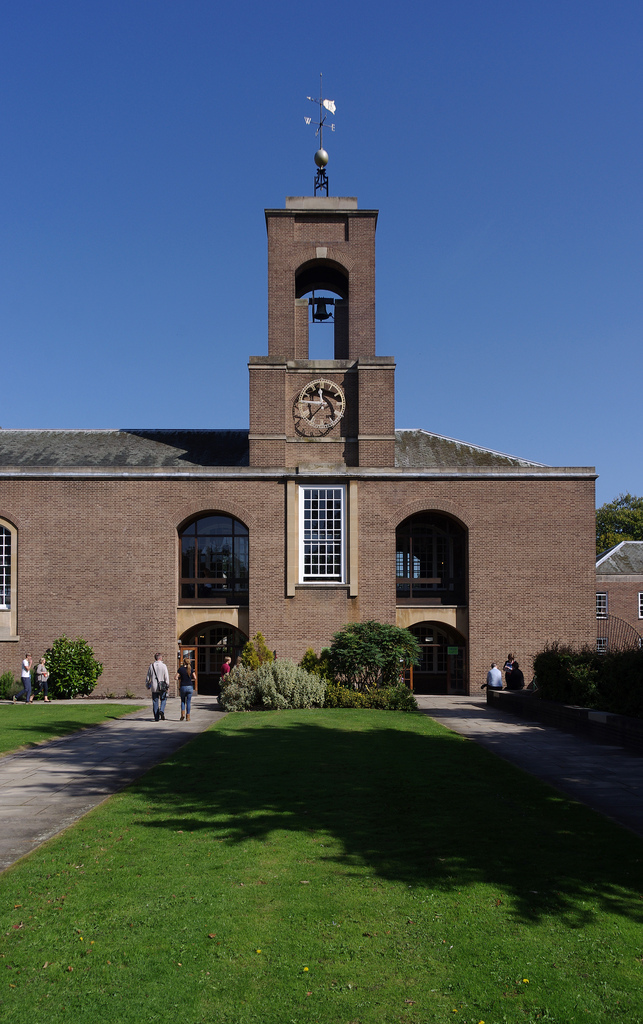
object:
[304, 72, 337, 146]
vane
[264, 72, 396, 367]
belfry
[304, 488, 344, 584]
window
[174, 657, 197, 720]
woman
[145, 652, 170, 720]
man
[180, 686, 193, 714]
denim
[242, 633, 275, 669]
tree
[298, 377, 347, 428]
clock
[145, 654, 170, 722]
people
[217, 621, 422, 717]
bushes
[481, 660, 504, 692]
people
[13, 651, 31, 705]
people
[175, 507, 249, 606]
window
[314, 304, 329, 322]
bell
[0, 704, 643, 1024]
grass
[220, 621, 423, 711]
landscaping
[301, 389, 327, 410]
hands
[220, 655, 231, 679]
person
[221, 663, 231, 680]
shirt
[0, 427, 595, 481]
roof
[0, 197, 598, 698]
building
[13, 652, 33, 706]
person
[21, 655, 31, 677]
shirt